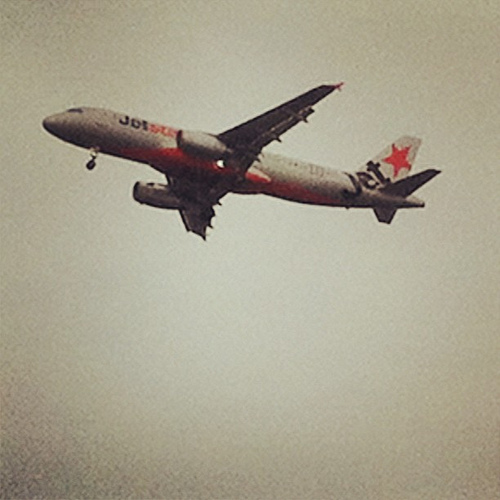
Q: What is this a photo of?
A: An airplane.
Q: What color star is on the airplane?
A: Red.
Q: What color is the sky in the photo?
A: White.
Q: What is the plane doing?
A: Flying.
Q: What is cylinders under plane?
A: Turbofan engine.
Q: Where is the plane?
A: In the air.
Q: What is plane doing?
A: Ascending.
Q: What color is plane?
A: Tan and red.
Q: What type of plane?
A: Commercial jet.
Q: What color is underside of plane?
A: Red.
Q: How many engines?
A: 2.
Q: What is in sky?
A: Blurry grey cloud.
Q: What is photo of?
A: White commercial airliner.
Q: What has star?
A: Tail of a plane.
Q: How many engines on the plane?
A: Two.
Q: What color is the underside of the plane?
A: Orange.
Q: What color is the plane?
A: Orange and white.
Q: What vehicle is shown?
A: A plane.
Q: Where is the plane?
A: In the sky.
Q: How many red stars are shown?
A: One.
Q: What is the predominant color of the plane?
A: White.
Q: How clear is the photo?
A: Not clear.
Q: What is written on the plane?
A: Jet.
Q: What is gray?
A: The sky.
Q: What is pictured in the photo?
A: Airplane.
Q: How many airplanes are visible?
A: 1.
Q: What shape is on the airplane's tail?
A: Star.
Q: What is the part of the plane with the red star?
A: Tail fin.